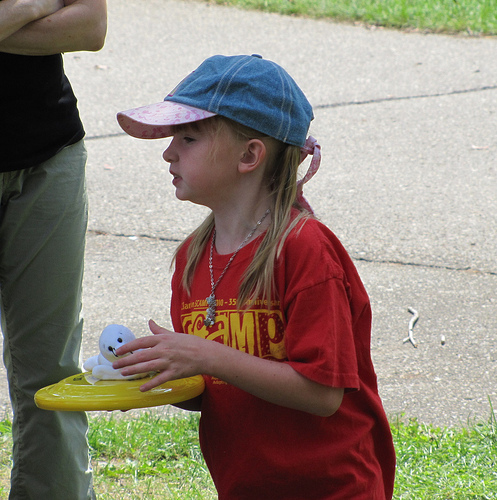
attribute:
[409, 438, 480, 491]
grass — green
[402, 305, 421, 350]
twig — broken, tree branch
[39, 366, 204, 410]
frisbee — shiny, yellow, toy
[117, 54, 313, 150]
cap — blue, ball cap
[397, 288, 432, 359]
twig — gray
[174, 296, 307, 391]
letters — yellow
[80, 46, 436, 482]
girl — little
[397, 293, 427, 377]
twig — gray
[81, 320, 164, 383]
toy — white, stuffed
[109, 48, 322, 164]
cap — blue, jean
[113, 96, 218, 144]
visor — pink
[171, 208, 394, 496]
tshirt — red, yellow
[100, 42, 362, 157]
cap — blue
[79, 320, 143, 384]
stuffed toy — white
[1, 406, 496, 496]
grass — green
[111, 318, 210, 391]
hand — girls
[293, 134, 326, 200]
strap — pink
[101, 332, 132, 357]
face — white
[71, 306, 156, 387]
toy — white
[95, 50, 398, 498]
girl — little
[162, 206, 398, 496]
t-shirt — red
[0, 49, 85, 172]
shirt — black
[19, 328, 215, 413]
frisbee — yellow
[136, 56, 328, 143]
hat — pink, blue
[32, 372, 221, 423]
frisbee — yellow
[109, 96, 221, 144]
bill — pink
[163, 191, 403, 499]
shirt — red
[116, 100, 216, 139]
rim — pink